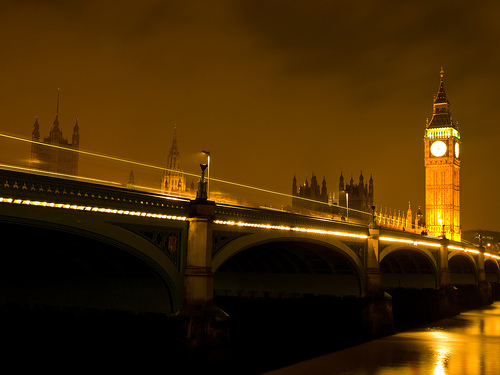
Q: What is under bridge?
A: Water.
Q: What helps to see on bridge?
A: Lights.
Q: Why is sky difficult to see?
A: Dark.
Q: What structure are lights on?
A: Bridge.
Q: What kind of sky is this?
A: Overcast sky.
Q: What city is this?
A: London.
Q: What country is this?
A: Great Britain.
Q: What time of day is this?
A: Evening.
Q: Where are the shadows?
A: Under bridge.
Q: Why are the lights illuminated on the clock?
A: It is night.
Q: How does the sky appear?
A: Overcast.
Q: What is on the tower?
A: Clocks.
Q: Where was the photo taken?
A: London.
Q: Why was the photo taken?
A: To capture a landmark.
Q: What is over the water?
A: Bridge.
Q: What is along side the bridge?
A: Lights.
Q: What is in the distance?
A: Castles.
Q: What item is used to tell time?
A: A clock.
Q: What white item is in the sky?
A: Clouds.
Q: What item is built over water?
A: A bridge.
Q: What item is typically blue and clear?
A: A sky.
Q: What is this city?
A: London.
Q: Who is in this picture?
A: Nobody.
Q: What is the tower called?
A: London clock tower.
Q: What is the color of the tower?
A: Gold.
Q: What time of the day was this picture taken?
A: Midnight.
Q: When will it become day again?
A: In 12 hours.